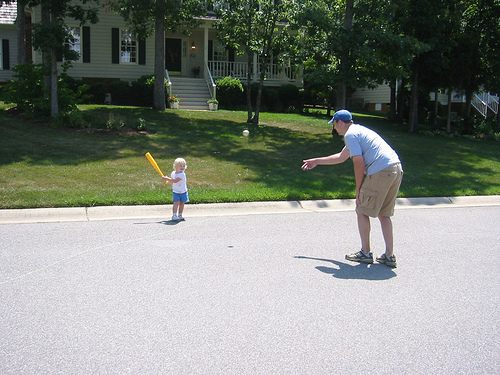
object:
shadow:
[292, 252, 400, 280]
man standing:
[299, 109, 405, 269]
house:
[0, 1, 500, 119]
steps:
[178, 105, 210, 108]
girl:
[160, 158, 189, 221]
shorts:
[172, 191, 190, 202]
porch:
[165, 22, 303, 77]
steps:
[176, 97, 206, 103]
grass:
[0, 99, 500, 207]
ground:
[0, 100, 499, 375]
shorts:
[353, 163, 403, 218]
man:
[300, 107, 404, 267]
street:
[2, 195, 499, 374]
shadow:
[133, 218, 187, 226]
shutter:
[228, 42, 236, 73]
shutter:
[110, 27, 122, 65]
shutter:
[1, 39, 12, 71]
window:
[61, 21, 84, 63]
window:
[82, 26, 94, 64]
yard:
[0, 100, 500, 210]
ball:
[240, 128, 249, 137]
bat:
[143, 151, 169, 183]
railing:
[208, 60, 287, 66]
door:
[164, 37, 184, 71]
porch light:
[188, 45, 198, 53]